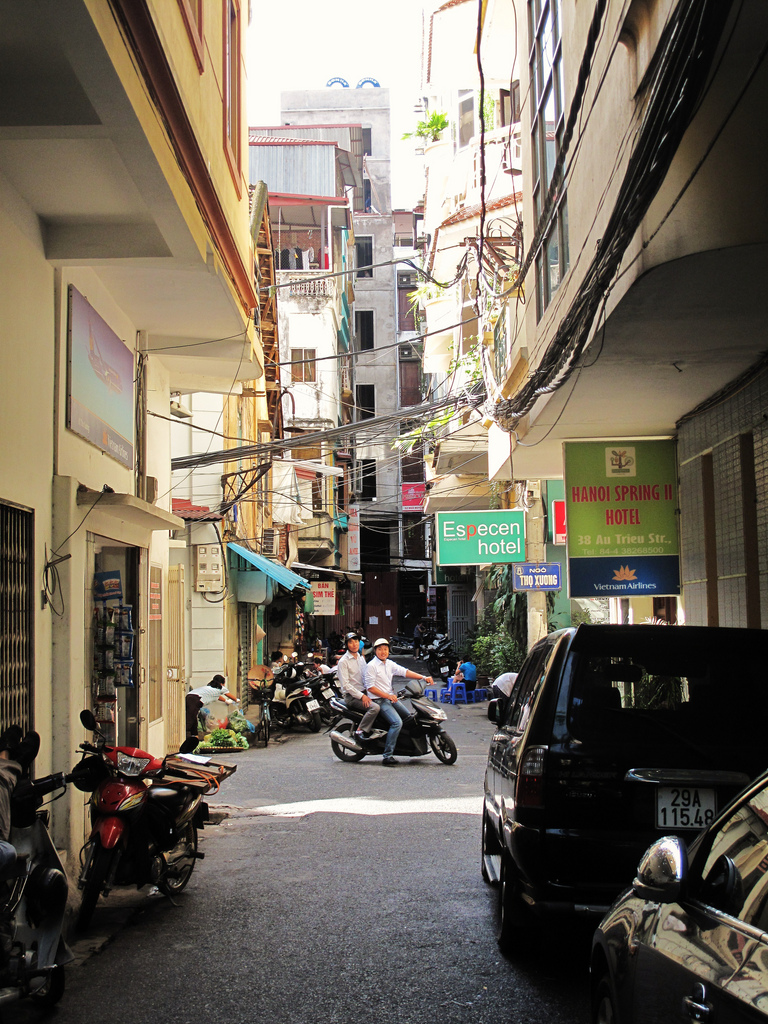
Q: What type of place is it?
A: It is a street.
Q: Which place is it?
A: It is a street.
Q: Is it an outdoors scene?
A: Yes, it is outdoors.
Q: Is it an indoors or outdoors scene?
A: It is outdoors.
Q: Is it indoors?
A: No, it is outdoors.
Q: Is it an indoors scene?
A: No, it is outdoors.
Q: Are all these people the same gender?
A: No, they are both male and female.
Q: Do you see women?
A: Yes, there is a woman.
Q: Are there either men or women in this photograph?
A: Yes, there is a woman.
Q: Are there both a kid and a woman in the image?
A: No, there is a woman but no children.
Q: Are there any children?
A: No, there are no children.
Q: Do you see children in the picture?
A: No, there are no children.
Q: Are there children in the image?
A: No, there are no children.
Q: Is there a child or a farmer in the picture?
A: No, there are no children or farmers.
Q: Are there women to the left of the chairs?
A: Yes, there is a woman to the left of the chairs.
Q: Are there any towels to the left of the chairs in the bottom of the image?
A: No, there is a woman to the left of the chairs.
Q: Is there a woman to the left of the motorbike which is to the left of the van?
A: Yes, there is a woman to the left of the motorbike.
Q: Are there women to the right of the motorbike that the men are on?
A: No, the woman is to the left of the motorbike.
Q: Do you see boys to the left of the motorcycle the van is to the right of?
A: No, there is a woman to the left of the motorbike.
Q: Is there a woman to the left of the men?
A: Yes, there is a woman to the left of the men.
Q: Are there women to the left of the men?
A: Yes, there is a woman to the left of the men.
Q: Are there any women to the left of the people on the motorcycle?
A: Yes, there is a woman to the left of the men.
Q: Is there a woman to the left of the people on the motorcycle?
A: Yes, there is a woman to the left of the men.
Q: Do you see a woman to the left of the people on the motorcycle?
A: Yes, there is a woman to the left of the men.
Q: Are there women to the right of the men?
A: No, the woman is to the left of the men.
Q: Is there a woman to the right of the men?
A: No, the woman is to the left of the men.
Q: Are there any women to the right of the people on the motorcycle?
A: No, the woman is to the left of the men.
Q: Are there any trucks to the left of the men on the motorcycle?
A: No, there is a woman to the left of the men.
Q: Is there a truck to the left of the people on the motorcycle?
A: No, there is a woman to the left of the men.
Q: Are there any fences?
A: No, there are no fences.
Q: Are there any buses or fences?
A: No, there are no fences or buses.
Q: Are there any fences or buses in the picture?
A: No, there are no fences or buses.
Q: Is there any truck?
A: No, there are no trucks.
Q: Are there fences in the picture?
A: No, there are no fences.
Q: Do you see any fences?
A: No, there are no fences.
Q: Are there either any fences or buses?
A: No, there are no fences or buses.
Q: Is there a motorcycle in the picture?
A: Yes, there is a motorcycle.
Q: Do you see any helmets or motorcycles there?
A: Yes, there is a motorcycle.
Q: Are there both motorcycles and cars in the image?
A: Yes, there are both a motorcycle and a car.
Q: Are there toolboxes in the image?
A: No, there are no toolboxes.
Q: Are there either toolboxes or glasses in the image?
A: No, there are no toolboxes or glasses.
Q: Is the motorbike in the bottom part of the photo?
A: Yes, the motorbike is in the bottom of the image.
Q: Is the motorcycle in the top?
A: No, the motorcycle is in the bottom of the image.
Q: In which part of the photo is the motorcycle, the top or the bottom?
A: The motorcycle is in the bottom of the image.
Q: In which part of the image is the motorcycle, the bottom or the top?
A: The motorcycle is in the bottom of the image.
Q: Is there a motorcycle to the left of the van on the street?
A: Yes, there is a motorcycle to the left of the van.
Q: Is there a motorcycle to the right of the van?
A: No, the motorcycle is to the left of the van.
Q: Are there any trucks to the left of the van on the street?
A: No, there is a motorcycle to the left of the van.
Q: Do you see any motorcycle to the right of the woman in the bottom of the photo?
A: Yes, there is a motorcycle to the right of the woman.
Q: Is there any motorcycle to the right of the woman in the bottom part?
A: Yes, there is a motorcycle to the right of the woman.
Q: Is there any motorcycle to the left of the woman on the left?
A: No, the motorcycle is to the right of the woman.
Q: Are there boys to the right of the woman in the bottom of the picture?
A: No, there is a motorcycle to the right of the woman.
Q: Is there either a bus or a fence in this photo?
A: No, there are no buses or fences.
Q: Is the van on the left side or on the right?
A: The van is on the right of the image.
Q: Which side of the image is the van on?
A: The van is on the right of the image.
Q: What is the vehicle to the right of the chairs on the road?
A: The vehicle is a van.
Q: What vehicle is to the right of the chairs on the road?
A: The vehicle is a van.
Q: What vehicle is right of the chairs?
A: The vehicle is a van.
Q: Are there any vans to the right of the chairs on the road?
A: Yes, there is a van to the right of the chairs.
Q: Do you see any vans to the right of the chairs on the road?
A: Yes, there is a van to the right of the chairs.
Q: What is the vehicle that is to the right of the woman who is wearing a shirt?
A: The vehicle is a van.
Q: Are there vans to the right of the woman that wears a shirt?
A: Yes, there is a van to the right of the woman.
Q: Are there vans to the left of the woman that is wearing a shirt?
A: No, the van is to the right of the woman.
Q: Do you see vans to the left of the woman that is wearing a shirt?
A: No, the van is to the right of the woman.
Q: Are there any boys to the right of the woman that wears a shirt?
A: No, there is a van to the right of the woman.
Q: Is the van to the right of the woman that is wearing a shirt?
A: Yes, the van is to the right of the woman.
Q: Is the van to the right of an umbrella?
A: No, the van is to the right of the woman.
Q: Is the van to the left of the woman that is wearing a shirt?
A: No, the van is to the right of the woman.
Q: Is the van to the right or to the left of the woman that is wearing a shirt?
A: The van is to the right of the woman.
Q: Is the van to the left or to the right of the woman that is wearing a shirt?
A: The van is to the right of the woman.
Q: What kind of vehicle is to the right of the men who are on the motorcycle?
A: The vehicle is a van.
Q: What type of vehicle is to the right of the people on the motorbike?
A: The vehicle is a van.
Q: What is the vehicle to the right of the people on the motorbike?
A: The vehicle is a van.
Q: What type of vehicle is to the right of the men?
A: The vehicle is a van.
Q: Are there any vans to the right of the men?
A: Yes, there is a van to the right of the men.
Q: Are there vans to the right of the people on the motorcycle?
A: Yes, there is a van to the right of the men.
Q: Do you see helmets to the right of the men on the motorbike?
A: No, there is a van to the right of the men.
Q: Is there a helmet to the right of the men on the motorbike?
A: No, there is a van to the right of the men.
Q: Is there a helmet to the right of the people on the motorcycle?
A: No, there is a van to the right of the men.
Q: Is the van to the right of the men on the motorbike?
A: Yes, the van is to the right of the men.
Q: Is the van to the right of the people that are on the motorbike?
A: Yes, the van is to the right of the men.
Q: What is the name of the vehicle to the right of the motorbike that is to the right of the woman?
A: The vehicle is a van.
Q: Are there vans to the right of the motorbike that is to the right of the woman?
A: Yes, there is a van to the right of the motorcycle.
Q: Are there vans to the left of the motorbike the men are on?
A: No, the van is to the right of the motorcycle.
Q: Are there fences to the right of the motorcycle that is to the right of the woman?
A: No, there is a van to the right of the motorbike.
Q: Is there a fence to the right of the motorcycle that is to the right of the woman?
A: No, there is a van to the right of the motorbike.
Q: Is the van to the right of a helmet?
A: No, the van is to the right of a motorcycle.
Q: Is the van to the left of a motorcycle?
A: No, the van is to the right of a motorcycle.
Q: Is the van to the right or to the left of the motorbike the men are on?
A: The van is to the right of the motorbike.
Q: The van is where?
A: The van is on the street.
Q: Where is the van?
A: The van is on the street.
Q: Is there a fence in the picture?
A: No, there are no fences.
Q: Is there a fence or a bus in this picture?
A: No, there are no fences or buses.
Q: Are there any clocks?
A: No, there are no clocks.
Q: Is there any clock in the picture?
A: No, there are no clocks.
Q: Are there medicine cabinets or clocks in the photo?
A: No, there are no clocks or medicine cabinets.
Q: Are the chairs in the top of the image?
A: No, the chairs are in the bottom of the image.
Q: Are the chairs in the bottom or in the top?
A: The chairs are in the bottom of the image.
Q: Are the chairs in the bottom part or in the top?
A: The chairs are in the bottom of the image.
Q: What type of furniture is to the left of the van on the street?
A: The pieces of furniture are chairs.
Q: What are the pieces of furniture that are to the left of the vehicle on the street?
A: The pieces of furniture are chairs.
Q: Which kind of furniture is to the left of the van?
A: The pieces of furniture are chairs.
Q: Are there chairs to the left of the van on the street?
A: Yes, there are chairs to the left of the van.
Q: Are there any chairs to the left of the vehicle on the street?
A: Yes, there are chairs to the left of the van.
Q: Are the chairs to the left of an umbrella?
A: No, the chairs are to the left of the van.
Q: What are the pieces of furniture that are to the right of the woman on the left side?
A: The pieces of furniture are chairs.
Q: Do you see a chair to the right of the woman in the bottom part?
A: Yes, there are chairs to the right of the woman.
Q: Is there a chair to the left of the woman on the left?
A: No, the chairs are to the right of the woman.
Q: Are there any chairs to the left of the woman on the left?
A: No, the chairs are to the right of the woman.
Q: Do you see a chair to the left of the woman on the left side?
A: No, the chairs are to the right of the woman.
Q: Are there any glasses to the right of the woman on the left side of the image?
A: No, there are chairs to the right of the woman.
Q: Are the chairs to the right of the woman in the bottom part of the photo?
A: Yes, the chairs are to the right of the woman.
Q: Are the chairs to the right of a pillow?
A: No, the chairs are to the right of the woman.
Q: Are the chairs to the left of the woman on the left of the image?
A: No, the chairs are to the right of the woman.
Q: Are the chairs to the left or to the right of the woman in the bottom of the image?
A: The chairs are to the right of the woman.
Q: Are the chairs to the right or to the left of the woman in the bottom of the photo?
A: The chairs are to the right of the woman.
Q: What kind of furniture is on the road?
A: The pieces of furniture are chairs.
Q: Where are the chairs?
A: The chairs are on the road.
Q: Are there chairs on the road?
A: Yes, there are chairs on the road.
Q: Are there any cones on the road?
A: No, there are chairs on the road.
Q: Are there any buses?
A: No, there are no buses.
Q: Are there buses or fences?
A: No, there are no buses or fences.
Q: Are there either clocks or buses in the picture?
A: No, there are no clocks or buses.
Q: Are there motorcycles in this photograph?
A: Yes, there is a motorcycle.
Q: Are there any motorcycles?
A: Yes, there is a motorcycle.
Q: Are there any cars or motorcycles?
A: Yes, there is a motorcycle.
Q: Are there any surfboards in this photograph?
A: No, there are no surfboards.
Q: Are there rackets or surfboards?
A: No, there are no surfboards or rackets.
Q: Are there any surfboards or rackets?
A: No, there are no surfboards or rackets.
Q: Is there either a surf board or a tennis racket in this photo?
A: No, there are no surfboards or rackets.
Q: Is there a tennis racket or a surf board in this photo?
A: No, there are no surfboards or rackets.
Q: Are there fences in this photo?
A: No, there are no fences.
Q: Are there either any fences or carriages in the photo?
A: No, there are no fences or carriages.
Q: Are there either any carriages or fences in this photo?
A: No, there are no fences or carriages.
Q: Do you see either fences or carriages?
A: No, there are no fences or carriages.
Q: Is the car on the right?
A: Yes, the car is on the right of the image.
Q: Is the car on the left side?
A: No, the car is on the right of the image.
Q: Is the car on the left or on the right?
A: The car is on the right of the image.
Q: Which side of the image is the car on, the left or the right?
A: The car is on the right of the image.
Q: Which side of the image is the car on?
A: The car is on the right of the image.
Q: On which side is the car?
A: The car is on the right of the image.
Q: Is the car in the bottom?
A: Yes, the car is in the bottom of the image.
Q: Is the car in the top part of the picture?
A: No, the car is in the bottom of the image.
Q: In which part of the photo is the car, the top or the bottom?
A: The car is in the bottom of the image.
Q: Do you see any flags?
A: No, there are no flags.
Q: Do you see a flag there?
A: No, there are no flags.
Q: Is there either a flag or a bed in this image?
A: No, there are no flags or beds.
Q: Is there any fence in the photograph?
A: No, there are no fences.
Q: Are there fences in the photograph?
A: No, there are no fences.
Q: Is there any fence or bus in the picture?
A: No, there are no fences or buses.